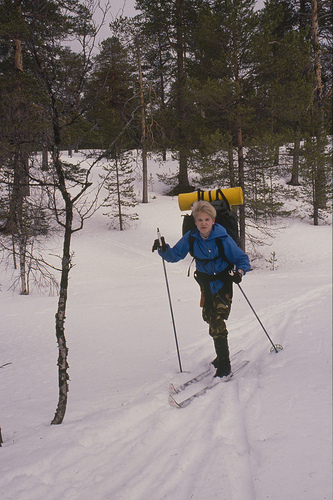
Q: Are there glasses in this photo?
A: No, there are no glasses.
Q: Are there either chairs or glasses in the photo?
A: No, there are no glasses or chairs.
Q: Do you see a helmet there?
A: No, there are no helmets.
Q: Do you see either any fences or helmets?
A: No, there are no helmets or fences.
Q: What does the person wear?
A: The person wears a backpack.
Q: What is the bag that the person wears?
A: The bag is a backpack.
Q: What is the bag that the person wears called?
A: The bag is a backpack.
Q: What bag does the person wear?
A: The person wears a backpack.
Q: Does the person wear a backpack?
A: Yes, the person wears a backpack.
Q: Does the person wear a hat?
A: No, the person wears a backpack.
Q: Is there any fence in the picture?
A: No, there are no fences.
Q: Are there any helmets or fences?
A: No, there are no fences or helmets.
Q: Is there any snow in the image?
A: Yes, there is snow.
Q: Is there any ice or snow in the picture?
A: Yes, there is snow.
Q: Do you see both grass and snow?
A: No, there is snow but no grass.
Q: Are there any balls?
A: No, there are no balls.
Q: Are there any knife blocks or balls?
A: No, there are no balls or knife blocks.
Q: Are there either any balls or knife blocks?
A: No, there are no balls or knife blocks.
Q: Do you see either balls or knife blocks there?
A: No, there are no balls or knife blocks.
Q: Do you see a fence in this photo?
A: No, there are no fences.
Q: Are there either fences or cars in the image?
A: No, there are no fences or cars.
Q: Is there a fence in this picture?
A: No, there are no fences.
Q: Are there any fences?
A: No, there are no fences.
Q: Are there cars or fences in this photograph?
A: No, there are no fences or cars.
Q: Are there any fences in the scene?
A: No, there are no fences.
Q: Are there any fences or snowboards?
A: No, there are no fences or snowboards.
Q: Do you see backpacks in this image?
A: Yes, there is a backpack.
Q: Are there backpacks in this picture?
A: Yes, there is a backpack.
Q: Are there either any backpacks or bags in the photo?
A: Yes, there is a backpack.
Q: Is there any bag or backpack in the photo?
A: Yes, there is a backpack.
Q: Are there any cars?
A: No, there are no cars.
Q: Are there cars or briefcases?
A: No, there are no cars or briefcases.